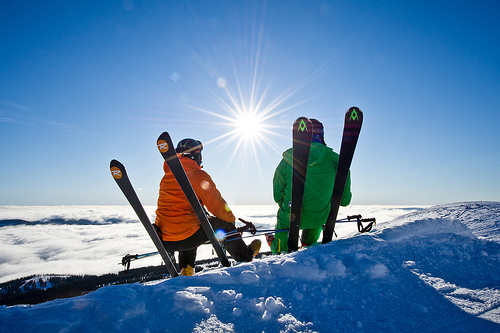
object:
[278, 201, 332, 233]
two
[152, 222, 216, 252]
sitting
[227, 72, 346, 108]
winter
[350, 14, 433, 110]
sky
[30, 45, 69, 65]
blue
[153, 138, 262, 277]
skiier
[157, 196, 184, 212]
orange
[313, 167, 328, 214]
green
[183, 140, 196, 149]
black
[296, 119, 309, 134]
decal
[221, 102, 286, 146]
sun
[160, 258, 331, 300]
down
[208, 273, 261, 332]
snow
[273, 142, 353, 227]
coat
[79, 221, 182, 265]
ground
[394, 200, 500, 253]
mountain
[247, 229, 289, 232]
poles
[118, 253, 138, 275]
bands